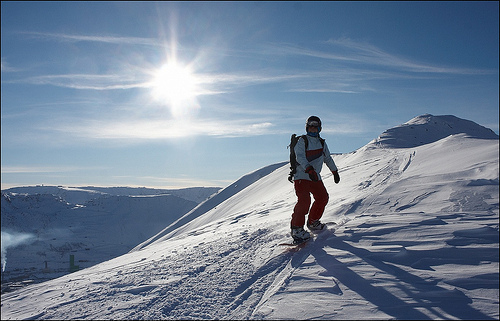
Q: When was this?
A: Daytime.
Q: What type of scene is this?
A: Outdoor scene.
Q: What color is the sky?
A: Blue.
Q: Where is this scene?
A: Mountain.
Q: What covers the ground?
A: Snow.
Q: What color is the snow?
A: White.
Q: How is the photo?
A: Clear.